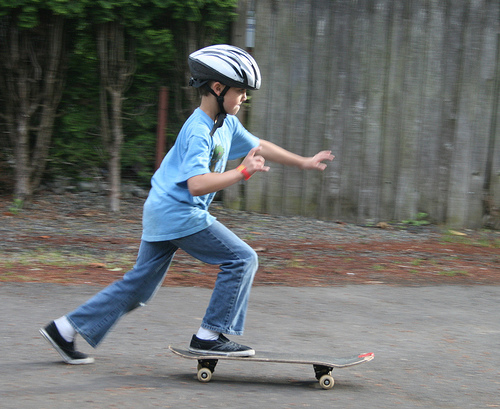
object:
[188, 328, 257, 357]
one foot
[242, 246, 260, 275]
knee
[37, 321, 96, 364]
shoe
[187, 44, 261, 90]
helmet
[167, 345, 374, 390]
skateboard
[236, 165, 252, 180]
wristband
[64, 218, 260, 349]
jeans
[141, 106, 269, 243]
shirt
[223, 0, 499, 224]
fence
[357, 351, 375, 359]
red tip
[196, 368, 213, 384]
wheel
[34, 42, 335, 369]
boy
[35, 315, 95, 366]
foot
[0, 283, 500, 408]
pavement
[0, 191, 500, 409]
ground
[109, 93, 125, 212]
trunk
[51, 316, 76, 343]
socks